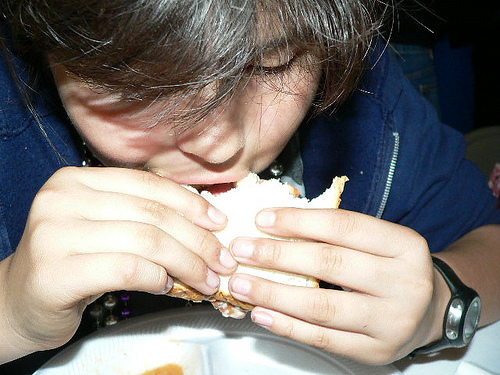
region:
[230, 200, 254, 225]
this is a bread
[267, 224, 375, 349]
these are the fingers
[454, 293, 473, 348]
this is the watch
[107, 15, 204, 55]
this is the hair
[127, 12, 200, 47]
the hair is black in colour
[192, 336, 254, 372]
this is the plate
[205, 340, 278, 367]
the plate is white in colour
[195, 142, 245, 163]
this is the nose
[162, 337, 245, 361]
the plate is circular in shape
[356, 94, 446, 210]
this is a sweater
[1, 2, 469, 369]
person eating a sandwich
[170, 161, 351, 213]
bites taken out of the sandwich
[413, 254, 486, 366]
black watch around the wrist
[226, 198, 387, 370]
fingers on the bread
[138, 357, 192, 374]
stain on the plate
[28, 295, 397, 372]
white styrofoam plate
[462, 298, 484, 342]
face of the watch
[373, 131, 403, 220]
silver zipper on the jadcket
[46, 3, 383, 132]
hair in the face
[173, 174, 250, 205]
mouth is open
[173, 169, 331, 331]
food to the mouth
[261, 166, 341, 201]
sandwich has been bitten into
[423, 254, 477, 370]
watch on left wrist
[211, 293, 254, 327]
meat on the sandwich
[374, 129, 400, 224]
silver zipper on jacket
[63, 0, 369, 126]
hair over eyes of person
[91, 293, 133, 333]
purple and silver beads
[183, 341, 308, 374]
plate is white that food is on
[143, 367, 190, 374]
brown drippings from sandwich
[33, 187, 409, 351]
two hands holding the food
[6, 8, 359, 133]
this is a girl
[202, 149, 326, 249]
this is a burger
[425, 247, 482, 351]
this is a wrist watch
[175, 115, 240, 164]
this is a nose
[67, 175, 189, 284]
these are the fingers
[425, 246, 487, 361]
the wrist watch is black in color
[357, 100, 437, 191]
this is a jacket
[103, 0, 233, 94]
this is a hair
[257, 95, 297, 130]
the lady is light skinned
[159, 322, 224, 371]
this is a plate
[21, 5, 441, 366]
A young boy eating a sandwich